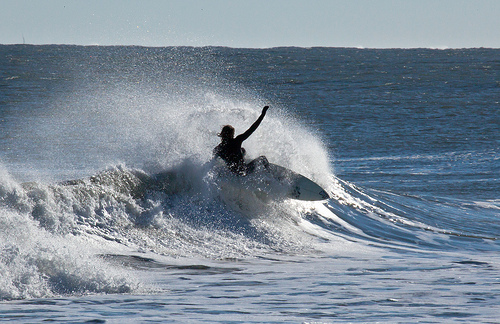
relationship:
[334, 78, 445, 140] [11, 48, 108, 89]
body of water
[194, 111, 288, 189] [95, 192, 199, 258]
person riding wave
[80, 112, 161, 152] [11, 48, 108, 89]
spray of water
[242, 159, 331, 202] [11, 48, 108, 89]
board in water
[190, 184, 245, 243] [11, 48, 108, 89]
suds in water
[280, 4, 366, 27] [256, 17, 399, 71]
sky in background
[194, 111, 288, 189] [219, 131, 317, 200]
persn's knee shown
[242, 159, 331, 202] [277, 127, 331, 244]
board of board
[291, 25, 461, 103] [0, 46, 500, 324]
edge of ocean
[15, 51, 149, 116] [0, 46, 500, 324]
side of ocean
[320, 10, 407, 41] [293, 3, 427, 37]
part of cloud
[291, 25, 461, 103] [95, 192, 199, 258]
edge of wave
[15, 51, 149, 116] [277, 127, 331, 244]
side of board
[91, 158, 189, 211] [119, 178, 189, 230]
ripples on surface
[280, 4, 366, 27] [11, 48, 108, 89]
sky above water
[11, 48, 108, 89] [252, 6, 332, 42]
water in air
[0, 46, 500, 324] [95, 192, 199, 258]
ocean on wave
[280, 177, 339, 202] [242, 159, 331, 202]
design on board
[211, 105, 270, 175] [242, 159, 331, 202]
person riding board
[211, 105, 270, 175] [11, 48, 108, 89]
person by water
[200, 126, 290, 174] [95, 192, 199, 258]
sufer on wave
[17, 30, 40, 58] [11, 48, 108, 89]
boat on water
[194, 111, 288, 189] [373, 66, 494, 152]
person out of ocean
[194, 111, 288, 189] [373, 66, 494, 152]
person in ocean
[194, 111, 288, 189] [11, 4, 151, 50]
person out of sunshine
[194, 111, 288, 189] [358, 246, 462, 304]
person close to beach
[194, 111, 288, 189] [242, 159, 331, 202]
person on board